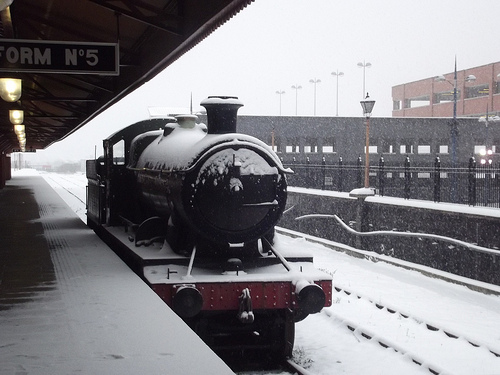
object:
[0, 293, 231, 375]
ground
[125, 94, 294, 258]
engine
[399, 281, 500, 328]
snow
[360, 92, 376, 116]
lamp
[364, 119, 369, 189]
post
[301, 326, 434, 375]
tracks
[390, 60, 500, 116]
building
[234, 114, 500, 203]
building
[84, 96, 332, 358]
black train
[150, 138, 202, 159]
snow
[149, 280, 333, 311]
front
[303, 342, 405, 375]
snow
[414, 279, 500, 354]
train track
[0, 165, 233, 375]
walkway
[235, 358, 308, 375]
train tracks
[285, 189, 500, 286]
fence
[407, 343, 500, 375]
tracks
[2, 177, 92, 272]
sidewalk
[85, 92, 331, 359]
train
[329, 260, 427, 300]
snow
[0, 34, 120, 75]
sign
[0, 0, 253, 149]
awning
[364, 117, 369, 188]
pole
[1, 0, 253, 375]
station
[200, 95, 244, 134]
stack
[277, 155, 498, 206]
fence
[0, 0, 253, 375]
train station